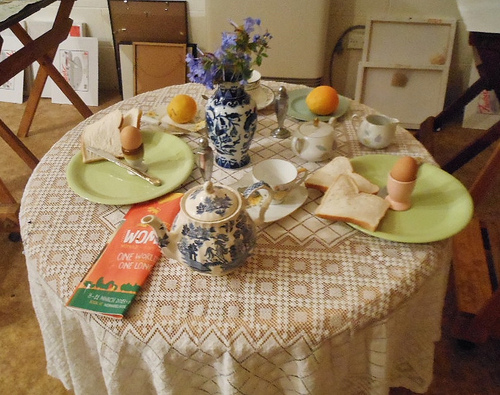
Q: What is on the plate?
A: An egg.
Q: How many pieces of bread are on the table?
A: Four.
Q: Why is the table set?
A: For breakfast.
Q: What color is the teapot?
A: Blue and white.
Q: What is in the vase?
A: Flowers.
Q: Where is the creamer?
A: Next to the sugar.